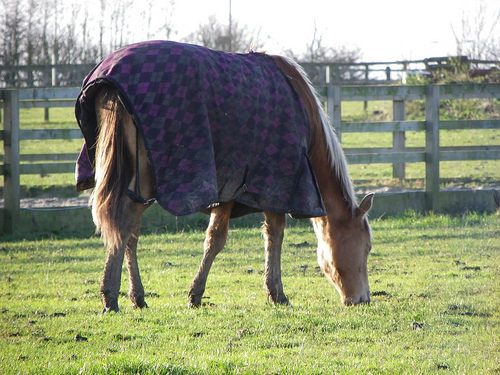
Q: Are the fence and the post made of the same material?
A: Yes, both the fence and the post are made of wood.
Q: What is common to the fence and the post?
A: The material, both the fence and the post are wooden.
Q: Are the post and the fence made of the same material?
A: Yes, both the post and the fence are made of wood.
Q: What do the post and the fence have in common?
A: The material, both the post and the fence are wooden.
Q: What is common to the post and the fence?
A: The material, both the post and the fence are wooden.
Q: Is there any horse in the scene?
A: Yes, there is a horse.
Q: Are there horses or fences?
A: Yes, there is a horse.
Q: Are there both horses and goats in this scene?
A: No, there is a horse but no goats.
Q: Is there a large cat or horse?
A: Yes, there is a large horse.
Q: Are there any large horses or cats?
A: Yes, there is a large horse.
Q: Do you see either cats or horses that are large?
A: Yes, the horse is large.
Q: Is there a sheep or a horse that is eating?
A: Yes, the horse is eating.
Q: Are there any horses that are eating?
A: Yes, there is a horse that is eating.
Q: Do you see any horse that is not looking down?
A: Yes, there is a horse that is eating .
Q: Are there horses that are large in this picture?
A: Yes, there is a large horse.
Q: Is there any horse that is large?
A: Yes, there is a horse that is large.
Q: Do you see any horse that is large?
A: Yes, there is a horse that is large.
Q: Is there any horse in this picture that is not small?
A: Yes, there is a large horse.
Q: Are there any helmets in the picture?
A: No, there are no helmets.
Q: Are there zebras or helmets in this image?
A: No, there are no helmets or zebras.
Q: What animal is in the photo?
A: The animal is a horse.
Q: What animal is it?
A: The animal is a horse.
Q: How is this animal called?
A: This is a horse.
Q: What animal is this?
A: This is a horse.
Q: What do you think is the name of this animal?
A: This is a horse.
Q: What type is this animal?
A: This is a horse.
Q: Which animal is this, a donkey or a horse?
A: This is a horse.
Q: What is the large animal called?
A: The animal is a horse.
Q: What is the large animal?
A: The animal is a horse.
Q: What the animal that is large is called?
A: The animal is a horse.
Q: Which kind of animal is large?
A: The animal is a horse.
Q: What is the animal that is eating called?
A: The animal is a horse.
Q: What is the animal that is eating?
A: The animal is a horse.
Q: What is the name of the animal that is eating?
A: The animal is a horse.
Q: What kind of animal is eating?
A: The animal is a horse.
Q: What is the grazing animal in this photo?
A: The animal is a horse.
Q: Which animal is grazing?
A: The animal is a horse.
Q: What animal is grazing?
A: The animal is a horse.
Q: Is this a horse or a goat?
A: This is a horse.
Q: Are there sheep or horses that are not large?
A: No, there is a horse but it is large.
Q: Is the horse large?
A: Yes, the horse is large.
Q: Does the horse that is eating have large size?
A: Yes, the horse is large.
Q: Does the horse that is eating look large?
A: Yes, the horse is large.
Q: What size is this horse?
A: The horse is large.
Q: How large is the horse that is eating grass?
A: The horse is large.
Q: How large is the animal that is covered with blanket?
A: The horse is large.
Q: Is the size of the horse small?
A: No, the horse is large.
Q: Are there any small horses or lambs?
A: No, there is a horse but it is large.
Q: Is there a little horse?
A: No, there is a horse but it is large.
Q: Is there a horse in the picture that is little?
A: No, there is a horse but it is large.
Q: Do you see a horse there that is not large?
A: No, there is a horse but it is large.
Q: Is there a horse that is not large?
A: No, there is a horse but it is large.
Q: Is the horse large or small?
A: The horse is large.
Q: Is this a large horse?
A: Yes, this is a large horse.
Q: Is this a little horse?
A: No, this is a large horse.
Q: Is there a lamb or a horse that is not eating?
A: No, there is a horse but it is eating.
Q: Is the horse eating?
A: Yes, the horse is eating.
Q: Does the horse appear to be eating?
A: Yes, the horse is eating.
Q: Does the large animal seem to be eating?
A: Yes, the horse is eating.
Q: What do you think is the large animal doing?
A: The horse is eating.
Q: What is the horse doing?
A: The horse is eating.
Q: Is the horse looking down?
A: No, the horse is eating.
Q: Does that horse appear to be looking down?
A: No, the horse is eating.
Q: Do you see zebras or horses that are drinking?
A: No, there is a horse but it is eating.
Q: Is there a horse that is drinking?
A: No, there is a horse but it is eating.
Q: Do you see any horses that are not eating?
A: No, there is a horse but it is eating.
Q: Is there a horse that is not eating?
A: No, there is a horse but it is eating.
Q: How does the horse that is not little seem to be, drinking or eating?
A: The horse is eating.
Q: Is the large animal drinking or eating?
A: The horse is eating.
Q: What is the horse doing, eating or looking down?
A: The horse is eating.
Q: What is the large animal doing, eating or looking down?
A: The horse is eating.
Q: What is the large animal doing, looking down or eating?
A: The horse is eating.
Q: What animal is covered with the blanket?
A: The horse is covered with blanket.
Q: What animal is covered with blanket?
A: The animal is a horse.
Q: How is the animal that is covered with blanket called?
A: The animal is a horse.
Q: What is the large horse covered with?
A: The horse is covered with blanket.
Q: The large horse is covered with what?
A: The horse is covered with blanket.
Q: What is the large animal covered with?
A: The horse is covered with blanket.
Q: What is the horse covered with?
A: The horse is covered with blanket.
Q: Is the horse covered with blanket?
A: Yes, the horse is covered with blanket.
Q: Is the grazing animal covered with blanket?
A: Yes, the horse is covered with blanket.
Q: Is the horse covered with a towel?
A: No, the horse is covered with blanket.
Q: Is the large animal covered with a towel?
A: No, the horse is covered with blanket.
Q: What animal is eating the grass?
A: The animal is a horse.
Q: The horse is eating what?
A: The horse is eating grass.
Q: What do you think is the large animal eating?
A: The horse is eating grass.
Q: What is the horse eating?
A: The horse is eating grass.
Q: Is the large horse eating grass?
A: Yes, the horse is eating grass.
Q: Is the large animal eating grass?
A: Yes, the horse is eating grass.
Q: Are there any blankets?
A: Yes, there is a blanket.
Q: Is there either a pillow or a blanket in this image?
A: Yes, there is a blanket.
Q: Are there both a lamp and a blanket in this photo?
A: No, there is a blanket but no lamps.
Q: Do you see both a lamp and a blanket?
A: No, there is a blanket but no lamps.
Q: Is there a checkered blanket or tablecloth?
A: Yes, there is a checkered blanket.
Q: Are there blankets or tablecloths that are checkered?
A: Yes, the blanket is checkered.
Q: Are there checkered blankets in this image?
A: Yes, there is a checkered blanket.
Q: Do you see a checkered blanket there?
A: Yes, there is a checkered blanket.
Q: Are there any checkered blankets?
A: Yes, there is a checkered blanket.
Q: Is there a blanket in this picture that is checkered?
A: Yes, there is a blanket that is checkered.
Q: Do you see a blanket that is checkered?
A: Yes, there is a blanket that is checkered.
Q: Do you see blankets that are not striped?
A: Yes, there is a checkered blanket.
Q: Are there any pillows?
A: No, there are no pillows.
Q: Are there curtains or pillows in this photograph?
A: No, there are no pillows or curtains.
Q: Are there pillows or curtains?
A: No, there are no pillows or curtains.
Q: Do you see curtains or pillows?
A: No, there are no pillows or curtains.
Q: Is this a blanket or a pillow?
A: This is a blanket.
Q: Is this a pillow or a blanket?
A: This is a blanket.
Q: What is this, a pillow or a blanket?
A: This is a blanket.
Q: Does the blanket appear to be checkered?
A: Yes, the blanket is checkered.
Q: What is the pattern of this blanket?
A: The blanket is checkered.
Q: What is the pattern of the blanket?
A: The blanket is checkered.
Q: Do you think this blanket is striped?
A: No, the blanket is checkered.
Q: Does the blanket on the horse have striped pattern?
A: No, the blanket is checkered.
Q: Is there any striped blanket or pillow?
A: No, there is a blanket but it is checkered.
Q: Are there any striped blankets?
A: No, there is a blanket but it is checkered.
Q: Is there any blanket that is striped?
A: No, there is a blanket but it is checkered.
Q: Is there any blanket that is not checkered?
A: No, there is a blanket but it is checkered.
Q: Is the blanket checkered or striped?
A: The blanket is checkered.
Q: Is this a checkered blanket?
A: Yes, this is a checkered blanket.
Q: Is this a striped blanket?
A: No, this is a checkered blanket.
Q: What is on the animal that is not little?
A: The blanket is on the horse.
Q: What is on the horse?
A: The blanket is on the horse.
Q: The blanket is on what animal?
A: The blanket is on the horse.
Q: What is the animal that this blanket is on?
A: The animal is a horse.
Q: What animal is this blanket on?
A: The blanket is on the horse.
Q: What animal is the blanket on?
A: The blanket is on the horse.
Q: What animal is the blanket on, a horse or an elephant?
A: The blanket is on a horse.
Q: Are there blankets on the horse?
A: Yes, there is a blanket on the horse.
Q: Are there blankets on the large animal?
A: Yes, there is a blanket on the horse.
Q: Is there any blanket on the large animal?
A: Yes, there is a blanket on the horse.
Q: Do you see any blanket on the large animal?
A: Yes, there is a blanket on the horse.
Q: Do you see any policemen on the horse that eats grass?
A: No, there is a blanket on the horse.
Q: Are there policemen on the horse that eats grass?
A: No, there is a blanket on the horse.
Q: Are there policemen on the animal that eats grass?
A: No, there is a blanket on the horse.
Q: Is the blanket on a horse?
A: Yes, the blanket is on a horse.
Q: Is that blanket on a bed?
A: No, the blanket is on a horse.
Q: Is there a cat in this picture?
A: No, there are no cats.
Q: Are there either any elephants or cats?
A: No, there are no cats or elephants.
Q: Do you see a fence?
A: Yes, there is a fence.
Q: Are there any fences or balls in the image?
A: Yes, there is a fence.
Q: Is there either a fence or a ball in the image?
A: Yes, there is a fence.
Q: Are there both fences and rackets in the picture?
A: No, there is a fence but no rackets.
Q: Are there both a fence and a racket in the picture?
A: No, there is a fence but no rackets.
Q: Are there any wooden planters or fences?
A: Yes, there is a wood fence.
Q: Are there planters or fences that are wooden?
A: Yes, the fence is wooden.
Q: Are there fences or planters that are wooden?
A: Yes, the fence is wooden.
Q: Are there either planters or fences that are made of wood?
A: Yes, the fence is made of wood.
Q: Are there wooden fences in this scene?
A: Yes, there is a wood fence.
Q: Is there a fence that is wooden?
A: Yes, there is a fence that is wooden.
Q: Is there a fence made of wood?
A: Yes, there is a fence that is made of wood.